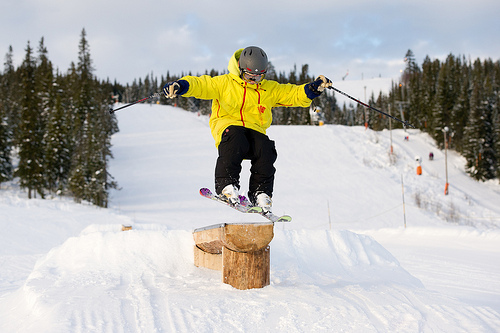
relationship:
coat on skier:
[176, 49, 323, 146] [162, 46, 334, 225]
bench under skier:
[192, 218, 276, 290] [162, 46, 334, 225]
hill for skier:
[25, 220, 431, 332] [162, 46, 334, 225]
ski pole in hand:
[324, 82, 416, 132] [315, 74, 335, 93]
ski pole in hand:
[105, 87, 180, 118] [162, 82, 181, 99]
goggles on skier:
[241, 72, 266, 82] [162, 46, 334, 225]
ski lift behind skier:
[313, 73, 452, 228] [162, 46, 334, 225]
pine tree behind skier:
[1, 26, 123, 210] [162, 46, 334, 225]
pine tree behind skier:
[353, 46, 500, 178] [162, 46, 334, 225]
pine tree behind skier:
[108, 60, 389, 130] [162, 46, 334, 225]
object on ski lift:
[414, 155, 423, 175] [313, 73, 452, 228]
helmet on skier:
[236, 46, 268, 74] [162, 46, 334, 225]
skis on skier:
[196, 185, 291, 223] [162, 46, 334, 225]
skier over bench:
[162, 46, 334, 225] [192, 218, 276, 290]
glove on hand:
[314, 75, 333, 91] [315, 74, 335, 93]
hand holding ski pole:
[315, 74, 335, 93] [324, 82, 416, 132]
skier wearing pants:
[162, 46, 334, 225] [212, 124, 277, 207]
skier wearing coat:
[162, 46, 334, 225] [176, 49, 323, 146]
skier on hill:
[162, 46, 334, 225] [25, 220, 431, 332]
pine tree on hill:
[108, 60, 389, 130] [25, 220, 431, 332]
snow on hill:
[0, 103, 495, 332] [25, 220, 431, 332]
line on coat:
[240, 81, 248, 127] [176, 49, 323, 146]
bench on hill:
[192, 218, 276, 290] [25, 220, 431, 332]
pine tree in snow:
[1, 26, 123, 210] [0, 103, 495, 332]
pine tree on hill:
[1, 26, 123, 210] [25, 220, 431, 332]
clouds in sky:
[157, 24, 197, 49] [1, 1, 499, 82]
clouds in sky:
[350, 52, 405, 66] [1, 1, 499, 82]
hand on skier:
[315, 74, 335, 93] [162, 46, 334, 225]